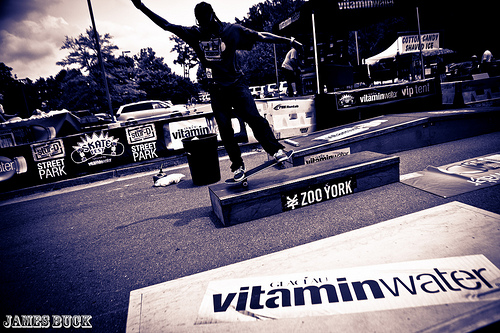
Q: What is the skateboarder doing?
A: Performing a trick.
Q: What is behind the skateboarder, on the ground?
A: A garbage bin.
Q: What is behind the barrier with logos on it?
A: A parking lot.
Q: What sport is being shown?
A: Skateboarding.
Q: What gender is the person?
A: Male.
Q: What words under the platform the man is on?
A: Zoo York.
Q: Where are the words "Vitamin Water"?
A: Ground.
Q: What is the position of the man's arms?
A: Out.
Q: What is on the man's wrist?
A: Watch.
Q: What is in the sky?
A: Clouds.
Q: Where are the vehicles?
A: Background behind the wall.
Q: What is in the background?
A: Trees.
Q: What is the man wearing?
A: A dark shirt.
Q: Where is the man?
A: In skateboarding area.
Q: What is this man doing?
A: Skateboarding.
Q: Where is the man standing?
A: On a skateboard.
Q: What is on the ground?
A: Logo.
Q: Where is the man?
A: On a skate ramp.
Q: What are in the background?
A: Cars.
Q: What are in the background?
A: Trees.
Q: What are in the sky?
A: Clouds.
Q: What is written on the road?
A: "vitaminwater".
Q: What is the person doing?
A: Skateboarding.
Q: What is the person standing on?
A: A skateboard.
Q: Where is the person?
A: At a skatepark.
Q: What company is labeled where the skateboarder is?
A: Zoo york.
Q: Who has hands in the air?
A: The skateboarder.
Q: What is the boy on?
A: Skateboard.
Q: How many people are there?
A: One.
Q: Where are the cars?
A: Parking lot.